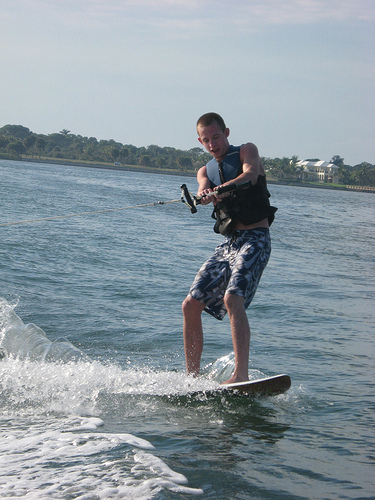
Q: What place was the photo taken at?
A: It was taken at the lake.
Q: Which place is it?
A: It is a lake.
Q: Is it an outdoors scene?
A: Yes, it is outdoors.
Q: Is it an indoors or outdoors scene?
A: It is outdoors.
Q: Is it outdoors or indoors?
A: It is outdoors.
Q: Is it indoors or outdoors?
A: It is outdoors.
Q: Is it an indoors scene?
A: No, it is outdoors.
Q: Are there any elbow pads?
A: No, there are no elbow pads.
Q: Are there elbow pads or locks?
A: No, there are no elbow pads or locks.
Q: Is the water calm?
A: Yes, the water is calm.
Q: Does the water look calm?
A: Yes, the water is calm.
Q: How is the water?
A: The water is calm.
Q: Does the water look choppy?
A: No, the water is calm.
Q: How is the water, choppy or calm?
A: The water is calm.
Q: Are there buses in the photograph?
A: No, there are no buses.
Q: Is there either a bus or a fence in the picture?
A: No, there are no buses or fences.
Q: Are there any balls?
A: No, there are no balls.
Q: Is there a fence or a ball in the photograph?
A: No, there are no balls or fences.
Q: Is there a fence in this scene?
A: No, there are no fences.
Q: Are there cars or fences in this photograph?
A: No, there are no fences or cars.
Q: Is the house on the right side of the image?
A: Yes, the house is on the right of the image.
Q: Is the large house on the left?
A: No, the house is on the right of the image.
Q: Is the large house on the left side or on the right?
A: The house is on the right of the image.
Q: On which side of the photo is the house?
A: The house is on the right of the image.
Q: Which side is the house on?
A: The house is on the right of the image.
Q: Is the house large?
A: Yes, the house is large.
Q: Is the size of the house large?
A: Yes, the house is large.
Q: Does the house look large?
A: Yes, the house is large.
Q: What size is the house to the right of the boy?
A: The house is large.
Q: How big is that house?
A: The house is large.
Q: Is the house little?
A: No, the house is large.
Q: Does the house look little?
A: No, the house is large.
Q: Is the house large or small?
A: The house is large.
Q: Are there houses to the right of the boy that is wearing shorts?
A: Yes, there is a house to the right of the boy.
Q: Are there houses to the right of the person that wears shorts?
A: Yes, there is a house to the right of the boy.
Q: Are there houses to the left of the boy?
A: No, the house is to the right of the boy.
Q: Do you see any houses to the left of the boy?
A: No, the house is to the right of the boy.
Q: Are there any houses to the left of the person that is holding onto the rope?
A: No, the house is to the right of the boy.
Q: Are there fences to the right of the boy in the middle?
A: No, there is a house to the right of the boy.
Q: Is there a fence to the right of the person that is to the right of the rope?
A: No, there is a house to the right of the boy.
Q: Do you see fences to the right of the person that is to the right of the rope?
A: No, there is a house to the right of the boy.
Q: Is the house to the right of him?
A: Yes, the house is to the right of the boy.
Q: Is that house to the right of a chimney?
A: No, the house is to the right of the boy.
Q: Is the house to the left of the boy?
A: No, the house is to the right of the boy.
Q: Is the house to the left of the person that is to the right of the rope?
A: No, the house is to the right of the boy.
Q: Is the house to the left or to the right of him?
A: The house is to the right of the boy.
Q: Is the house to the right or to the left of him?
A: The house is to the right of the boy.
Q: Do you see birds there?
A: No, there are no birds.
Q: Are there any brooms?
A: No, there are no brooms.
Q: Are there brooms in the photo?
A: No, there are no brooms.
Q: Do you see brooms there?
A: No, there are no brooms.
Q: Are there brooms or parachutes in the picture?
A: No, there are no brooms or parachutes.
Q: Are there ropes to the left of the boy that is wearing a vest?
A: Yes, there is a rope to the left of the boy.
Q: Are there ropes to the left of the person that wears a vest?
A: Yes, there is a rope to the left of the boy.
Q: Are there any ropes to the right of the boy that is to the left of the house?
A: No, the rope is to the left of the boy.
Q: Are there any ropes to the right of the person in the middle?
A: No, the rope is to the left of the boy.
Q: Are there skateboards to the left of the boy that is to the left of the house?
A: No, there is a rope to the left of the boy.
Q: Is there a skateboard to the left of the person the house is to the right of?
A: No, there is a rope to the left of the boy.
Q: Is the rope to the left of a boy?
A: Yes, the rope is to the left of a boy.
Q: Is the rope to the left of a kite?
A: No, the rope is to the left of a boy.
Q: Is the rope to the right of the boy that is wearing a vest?
A: No, the rope is to the left of the boy.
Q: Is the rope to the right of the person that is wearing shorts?
A: No, the rope is to the left of the boy.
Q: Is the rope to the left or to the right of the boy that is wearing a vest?
A: The rope is to the left of the boy.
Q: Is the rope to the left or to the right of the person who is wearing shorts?
A: The rope is to the left of the boy.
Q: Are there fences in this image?
A: No, there are no fences.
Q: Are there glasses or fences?
A: No, there are no fences or glasses.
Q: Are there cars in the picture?
A: No, there are no cars.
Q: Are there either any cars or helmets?
A: No, there are no cars or helmets.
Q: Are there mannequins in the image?
A: No, there are no mannequins.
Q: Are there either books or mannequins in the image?
A: No, there are no mannequins or books.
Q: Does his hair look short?
A: Yes, the hair is short.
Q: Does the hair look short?
A: Yes, the hair is short.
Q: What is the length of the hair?
A: The hair is short.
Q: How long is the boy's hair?
A: The hair is short.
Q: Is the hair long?
A: No, the hair is short.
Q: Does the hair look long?
A: No, the hair is short.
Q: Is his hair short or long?
A: The hair is short.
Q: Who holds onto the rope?
A: The boy holds onto the rope.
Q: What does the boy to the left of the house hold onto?
A: The boy holds onto the rope.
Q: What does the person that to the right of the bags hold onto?
A: The boy holds onto the rope.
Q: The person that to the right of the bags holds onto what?
A: The boy holds onto the rope.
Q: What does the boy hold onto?
A: The boy holds onto the rope.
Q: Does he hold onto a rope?
A: Yes, the boy holds onto a rope.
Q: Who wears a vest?
A: The boy wears a vest.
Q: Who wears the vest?
A: The boy wears a vest.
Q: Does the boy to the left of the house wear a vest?
A: Yes, the boy wears a vest.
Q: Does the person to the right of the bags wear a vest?
A: Yes, the boy wears a vest.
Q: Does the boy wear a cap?
A: No, the boy wears a vest.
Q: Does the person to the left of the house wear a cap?
A: No, the boy wears a vest.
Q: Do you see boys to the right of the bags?
A: Yes, there is a boy to the right of the bags.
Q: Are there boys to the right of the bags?
A: Yes, there is a boy to the right of the bags.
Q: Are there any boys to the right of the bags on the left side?
A: Yes, there is a boy to the right of the bags.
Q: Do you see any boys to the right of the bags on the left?
A: Yes, there is a boy to the right of the bags.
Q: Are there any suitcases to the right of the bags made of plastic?
A: No, there is a boy to the right of the bags.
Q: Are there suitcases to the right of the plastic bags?
A: No, there is a boy to the right of the bags.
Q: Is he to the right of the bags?
A: Yes, the boy is to the right of the bags.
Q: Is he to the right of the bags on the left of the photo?
A: Yes, the boy is to the right of the bags.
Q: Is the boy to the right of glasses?
A: No, the boy is to the right of the bags.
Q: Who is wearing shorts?
A: The boy is wearing shorts.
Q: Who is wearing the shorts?
A: The boy is wearing shorts.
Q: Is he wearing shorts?
A: Yes, the boy is wearing shorts.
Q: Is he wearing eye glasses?
A: No, the boy is wearing shorts.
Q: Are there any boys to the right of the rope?
A: Yes, there is a boy to the right of the rope.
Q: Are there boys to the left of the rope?
A: No, the boy is to the right of the rope.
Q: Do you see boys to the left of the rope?
A: No, the boy is to the right of the rope.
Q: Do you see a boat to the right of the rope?
A: No, there is a boy to the right of the rope.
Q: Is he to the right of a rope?
A: Yes, the boy is to the right of a rope.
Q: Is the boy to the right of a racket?
A: No, the boy is to the right of a rope.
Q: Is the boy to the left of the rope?
A: No, the boy is to the right of the rope.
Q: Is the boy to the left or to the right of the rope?
A: The boy is to the right of the rope.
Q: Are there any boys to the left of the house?
A: Yes, there is a boy to the left of the house.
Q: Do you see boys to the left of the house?
A: Yes, there is a boy to the left of the house.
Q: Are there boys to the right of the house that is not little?
A: No, the boy is to the left of the house.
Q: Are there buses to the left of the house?
A: No, there is a boy to the left of the house.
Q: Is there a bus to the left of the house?
A: No, there is a boy to the left of the house.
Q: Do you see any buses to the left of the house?
A: No, there is a boy to the left of the house.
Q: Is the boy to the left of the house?
A: Yes, the boy is to the left of the house.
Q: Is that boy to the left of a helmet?
A: No, the boy is to the left of the house.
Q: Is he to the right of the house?
A: No, the boy is to the left of the house.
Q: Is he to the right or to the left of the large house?
A: The boy is to the left of the house.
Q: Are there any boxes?
A: No, there are no boxes.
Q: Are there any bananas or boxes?
A: No, there are no boxes or bananas.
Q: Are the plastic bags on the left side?
A: Yes, the bags are on the left of the image.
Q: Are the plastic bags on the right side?
A: No, the bags are on the left of the image.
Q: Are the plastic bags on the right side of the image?
A: No, the bags are on the left of the image.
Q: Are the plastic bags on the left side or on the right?
A: The bags are on the left of the image.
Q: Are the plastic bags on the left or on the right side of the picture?
A: The bags are on the left of the image.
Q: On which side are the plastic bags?
A: The bags are on the left of the image.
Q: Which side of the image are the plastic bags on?
A: The bags are on the left of the image.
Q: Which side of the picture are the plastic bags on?
A: The bags are on the left of the image.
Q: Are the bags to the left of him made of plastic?
A: Yes, the bags are made of plastic.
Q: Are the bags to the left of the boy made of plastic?
A: Yes, the bags are made of plastic.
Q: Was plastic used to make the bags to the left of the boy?
A: Yes, the bags are made of plastic.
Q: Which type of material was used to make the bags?
A: The bags are made of plastic.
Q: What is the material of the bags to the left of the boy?
A: The bags are made of plastic.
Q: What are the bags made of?
A: The bags are made of plastic.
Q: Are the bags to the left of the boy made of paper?
A: No, the bags are made of plastic.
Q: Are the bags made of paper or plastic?
A: The bags are made of plastic.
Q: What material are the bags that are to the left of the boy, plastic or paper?
A: The bags are made of plastic.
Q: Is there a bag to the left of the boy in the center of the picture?
A: Yes, there are bags to the left of the boy.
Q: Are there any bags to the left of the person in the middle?
A: Yes, there are bags to the left of the boy.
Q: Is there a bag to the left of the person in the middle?
A: Yes, there are bags to the left of the boy.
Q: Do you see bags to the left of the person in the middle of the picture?
A: Yes, there are bags to the left of the boy.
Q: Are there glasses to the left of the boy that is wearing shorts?
A: No, there are bags to the left of the boy.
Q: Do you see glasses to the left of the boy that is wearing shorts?
A: No, there are bags to the left of the boy.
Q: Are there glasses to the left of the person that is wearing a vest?
A: No, there are bags to the left of the boy.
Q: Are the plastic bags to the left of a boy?
A: Yes, the bags are to the left of a boy.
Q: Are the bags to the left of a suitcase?
A: No, the bags are to the left of a boy.